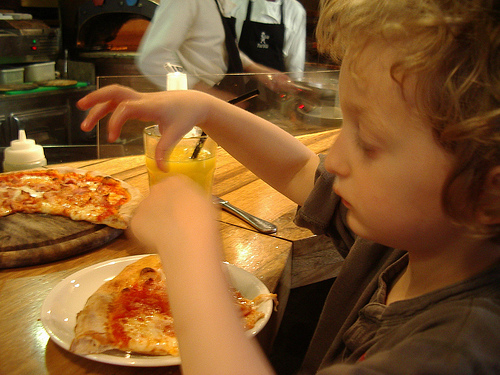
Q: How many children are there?
A: One.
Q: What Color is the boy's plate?
A: White.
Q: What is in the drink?
A: Straw.